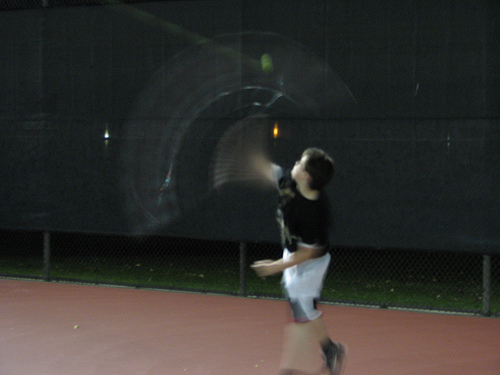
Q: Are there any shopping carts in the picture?
A: No, there are no shopping carts.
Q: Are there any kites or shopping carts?
A: No, there are no shopping carts or kites.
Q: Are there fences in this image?
A: Yes, there is a fence.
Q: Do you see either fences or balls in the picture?
A: Yes, there is a fence.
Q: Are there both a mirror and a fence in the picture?
A: No, there is a fence but no mirrors.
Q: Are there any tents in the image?
A: No, there are no tents.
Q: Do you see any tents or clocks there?
A: No, there are no tents or clocks.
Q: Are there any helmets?
A: No, there are no helmets.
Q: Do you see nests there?
A: No, there are no nests.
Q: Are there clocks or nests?
A: No, there are no nests or clocks.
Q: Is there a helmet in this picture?
A: No, there are no helmets.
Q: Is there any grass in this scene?
A: Yes, there is grass.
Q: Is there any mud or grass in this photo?
A: Yes, there is grass.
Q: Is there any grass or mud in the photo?
A: Yes, there is grass.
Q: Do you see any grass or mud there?
A: Yes, there is grass.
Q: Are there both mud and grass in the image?
A: No, there is grass but no mud.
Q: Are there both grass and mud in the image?
A: No, there is grass but no mud.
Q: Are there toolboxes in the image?
A: No, there are no toolboxes.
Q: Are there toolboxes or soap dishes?
A: No, there are no toolboxes or soap dishes.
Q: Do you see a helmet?
A: No, there are no helmets.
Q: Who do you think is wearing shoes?
A: The boy is wearing shoes.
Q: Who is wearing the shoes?
A: The boy is wearing shoes.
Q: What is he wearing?
A: The boy is wearing shoes.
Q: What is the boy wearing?
A: The boy is wearing shoes.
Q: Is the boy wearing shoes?
A: Yes, the boy is wearing shoes.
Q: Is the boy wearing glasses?
A: No, the boy is wearing shoes.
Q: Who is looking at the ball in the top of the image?
A: The boy is looking at the ball.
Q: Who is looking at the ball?
A: The boy is looking at the ball.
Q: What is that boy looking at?
A: The boy is looking at the ball.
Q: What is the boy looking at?
A: The boy is looking at the ball.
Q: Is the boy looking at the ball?
A: Yes, the boy is looking at the ball.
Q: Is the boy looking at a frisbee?
A: No, the boy is looking at the ball.